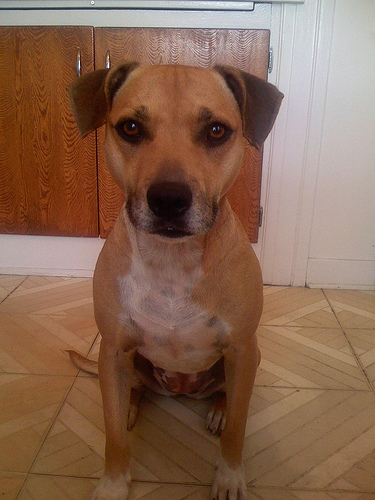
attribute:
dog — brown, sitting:
[55, 57, 258, 493]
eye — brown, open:
[101, 101, 162, 156]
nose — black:
[136, 152, 195, 214]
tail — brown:
[75, 340, 114, 388]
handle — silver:
[62, 51, 87, 79]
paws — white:
[85, 446, 268, 498]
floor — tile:
[0, 293, 84, 443]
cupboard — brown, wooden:
[0, 28, 90, 247]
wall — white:
[284, 11, 346, 229]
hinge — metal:
[254, 30, 279, 78]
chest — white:
[121, 220, 206, 382]